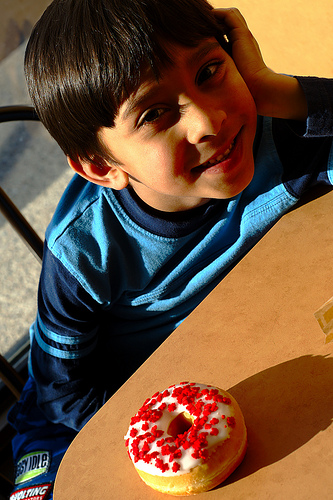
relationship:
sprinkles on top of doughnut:
[123, 382, 236, 473] [125, 380, 247, 496]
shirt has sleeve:
[8, 77, 330, 429] [26, 237, 114, 433]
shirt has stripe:
[8, 77, 330, 429] [34, 321, 94, 352]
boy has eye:
[8, 0, 329, 499] [132, 99, 172, 132]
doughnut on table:
[125, 380, 247, 496] [29, 230, 332, 500]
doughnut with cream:
[125, 380, 247, 496] [126, 380, 231, 477]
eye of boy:
[132, 99, 172, 132] [9, 49, 331, 284]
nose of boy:
[187, 88, 228, 144] [14, 51, 319, 329]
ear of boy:
[66, 147, 128, 190] [14, 51, 319, 329]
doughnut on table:
[125, 380, 248, 496] [51, 186, 333, 498]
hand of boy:
[17, 244, 103, 497] [8, 0, 329, 499]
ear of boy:
[66, 147, 128, 190] [9, 36, 329, 257]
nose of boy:
[187, 88, 228, 144] [9, 49, 331, 284]